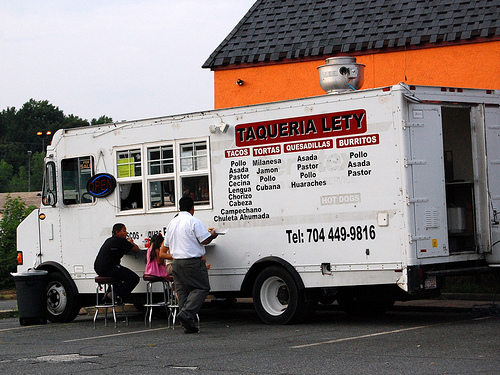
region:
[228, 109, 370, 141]
A "Taqueria Lety" truck.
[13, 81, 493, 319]
A white food truck.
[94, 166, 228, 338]
Three people eating food.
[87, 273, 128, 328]
A metal bar stool.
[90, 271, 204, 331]
Three metal bar stools.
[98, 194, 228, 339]
Four people eating food.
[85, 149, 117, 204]
A hat hanging from the food truck.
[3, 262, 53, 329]
A green trash can.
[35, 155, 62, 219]
The side mirrors of a food truck.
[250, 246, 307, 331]
The back tire of a food truck.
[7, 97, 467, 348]
food truck serving customers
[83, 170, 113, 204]
open sign on the food truck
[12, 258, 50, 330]
trash can by the tire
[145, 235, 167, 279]
little girl sitting on a stool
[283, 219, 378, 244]
telephone number on the truck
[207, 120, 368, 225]
menu on the truck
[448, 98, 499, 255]
back door on truck is open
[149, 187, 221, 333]
man is walking toward truck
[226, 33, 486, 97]
building behind the truck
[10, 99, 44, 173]
trees behind the truck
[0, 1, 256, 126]
cloud cover in sky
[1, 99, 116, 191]
green leaves on trees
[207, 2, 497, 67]
shingles on slanted roof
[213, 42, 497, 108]
orange wall of building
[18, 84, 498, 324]
side of food truck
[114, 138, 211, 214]
three windows on truck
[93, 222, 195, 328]
people sitting on stools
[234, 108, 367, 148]
two words on red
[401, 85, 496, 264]
open door on back of truck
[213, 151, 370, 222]
black words on white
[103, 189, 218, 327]
People on side of the truck.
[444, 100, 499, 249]
The door of the truck is open.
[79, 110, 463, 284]
Food truck in the parking lot.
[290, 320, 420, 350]
White line on the road.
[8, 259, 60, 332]
Garbage can by the truck.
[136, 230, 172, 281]
Little girl sitting on the stool.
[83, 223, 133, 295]
A man sitting on the stool.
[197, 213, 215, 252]
A man with food in his hands.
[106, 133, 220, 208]
The window for ordering.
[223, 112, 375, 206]
Writing on the food truck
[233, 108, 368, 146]
red black and white food truck sign TAQUERIA LETY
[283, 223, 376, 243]
telephone number in black lettering on white food truck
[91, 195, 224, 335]
taco food truck patrons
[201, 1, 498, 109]
orange building with dark roof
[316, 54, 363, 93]
roof-mounted food truck exhaust fan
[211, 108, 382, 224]
food truck menu painted on side of truck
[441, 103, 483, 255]
open door to interior of food truck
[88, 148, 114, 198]
red blue and black OPEN electric sign on food truck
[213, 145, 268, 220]
list of taco menu items on side of taco truck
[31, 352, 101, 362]
hole in asphalt parking lot